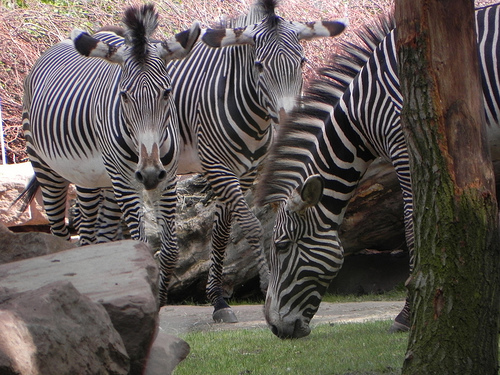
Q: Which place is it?
A: It is a park.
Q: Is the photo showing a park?
A: Yes, it is showing a park.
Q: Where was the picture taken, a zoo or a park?
A: It was taken at a park.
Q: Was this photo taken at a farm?
A: No, the picture was taken in a park.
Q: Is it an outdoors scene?
A: Yes, it is outdoors.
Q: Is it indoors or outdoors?
A: It is outdoors.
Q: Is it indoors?
A: No, it is outdoors.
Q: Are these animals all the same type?
A: Yes, all the animals are zebras.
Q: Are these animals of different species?
A: No, all the animals are zebras.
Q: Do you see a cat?
A: No, there are no cats.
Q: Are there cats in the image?
A: No, there are no cats.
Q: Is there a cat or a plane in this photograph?
A: No, there are no cats or airplanes.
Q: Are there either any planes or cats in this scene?
A: No, there are no cats or planes.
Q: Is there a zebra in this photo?
A: Yes, there is a zebra.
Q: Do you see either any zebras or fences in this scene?
A: Yes, there is a zebra.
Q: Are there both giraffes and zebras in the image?
A: No, there is a zebra but no giraffes.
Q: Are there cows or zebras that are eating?
A: Yes, the zebra is eating.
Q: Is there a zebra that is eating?
A: Yes, there is a zebra that is eating.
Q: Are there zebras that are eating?
A: Yes, there is a zebra that is eating.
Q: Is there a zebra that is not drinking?
A: Yes, there is a zebra that is eating.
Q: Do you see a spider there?
A: No, there are no spiders.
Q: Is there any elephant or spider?
A: No, there are no spiders or elephants.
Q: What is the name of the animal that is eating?
A: The animal is a zebra.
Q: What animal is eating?
A: The animal is a zebra.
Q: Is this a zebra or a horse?
A: This is a zebra.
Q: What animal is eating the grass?
A: The animal is a zebra.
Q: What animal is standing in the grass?
A: The animal is a zebra.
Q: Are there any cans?
A: No, there are no cans.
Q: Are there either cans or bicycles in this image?
A: No, there are no cans or bicycles.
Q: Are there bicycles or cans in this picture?
A: No, there are no cans or bicycles.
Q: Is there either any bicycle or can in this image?
A: No, there are no cans or bicycles.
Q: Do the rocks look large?
A: Yes, the rocks are large.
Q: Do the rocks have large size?
A: Yes, the rocks are large.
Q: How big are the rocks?
A: The rocks are large.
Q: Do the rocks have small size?
A: No, the rocks are large.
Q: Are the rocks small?
A: No, the rocks are large.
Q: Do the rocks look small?
A: No, the rocks are large.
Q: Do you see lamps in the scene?
A: No, there are no lamps.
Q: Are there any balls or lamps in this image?
A: No, there are no lamps or balls.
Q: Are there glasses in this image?
A: No, there are no glasses.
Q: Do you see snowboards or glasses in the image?
A: No, there are no glasses or snowboards.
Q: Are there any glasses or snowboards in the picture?
A: No, there are no glasses or snowboards.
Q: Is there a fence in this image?
A: No, there are no fences.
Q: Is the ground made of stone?
A: Yes, the ground is made of stone.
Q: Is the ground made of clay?
A: No, the ground is made of stone.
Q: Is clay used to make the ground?
A: No, the ground is made of stone.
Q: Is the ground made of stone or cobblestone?
A: The ground is made of stone.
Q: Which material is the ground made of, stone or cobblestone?
A: The ground is made of stone.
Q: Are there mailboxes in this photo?
A: No, there are no mailboxes.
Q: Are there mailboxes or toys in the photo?
A: No, there are no mailboxes or toys.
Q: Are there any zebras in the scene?
A: Yes, there are zebras.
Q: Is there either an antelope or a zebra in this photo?
A: Yes, there are zebras.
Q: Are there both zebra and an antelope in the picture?
A: No, there are zebras but no antelopes.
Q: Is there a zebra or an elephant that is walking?
A: Yes, the zebras are walking.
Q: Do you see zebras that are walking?
A: Yes, there are zebras that are walking.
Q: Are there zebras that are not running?
A: Yes, there are zebras that are walking.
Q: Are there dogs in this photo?
A: No, there are no dogs.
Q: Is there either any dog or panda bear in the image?
A: No, there are no dogs or panda bears.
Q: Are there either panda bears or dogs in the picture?
A: No, there are no dogs or panda bears.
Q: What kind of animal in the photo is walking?
A: The animal is zebras.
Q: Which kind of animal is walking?
A: The animal is zebras.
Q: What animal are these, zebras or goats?
A: These are zebras.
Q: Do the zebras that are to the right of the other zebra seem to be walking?
A: Yes, the zebras are walking.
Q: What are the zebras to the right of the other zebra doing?
A: The zebras are walking.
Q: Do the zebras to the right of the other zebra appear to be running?
A: No, the zebras are walking.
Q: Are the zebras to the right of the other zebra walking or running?
A: The zebras are walking.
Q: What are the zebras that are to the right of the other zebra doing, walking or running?
A: The zebras are walking.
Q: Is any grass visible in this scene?
A: Yes, there is grass.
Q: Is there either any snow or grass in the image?
A: Yes, there is grass.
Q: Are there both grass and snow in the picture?
A: No, there is grass but no snow.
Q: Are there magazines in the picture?
A: No, there are no magazines.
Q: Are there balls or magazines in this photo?
A: No, there are no magazines or balls.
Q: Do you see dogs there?
A: No, there are no dogs.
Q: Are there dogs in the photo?
A: No, there are no dogs.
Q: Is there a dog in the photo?
A: No, there are no dogs.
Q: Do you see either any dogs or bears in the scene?
A: No, there are no dogs or bears.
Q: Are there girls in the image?
A: No, there are no girls.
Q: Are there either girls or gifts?
A: No, there are no girls or gifts.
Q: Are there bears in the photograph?
A: No, there are no bears.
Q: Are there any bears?
A: No, there are no bears.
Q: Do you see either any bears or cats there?
A: No, there are no bears or cats.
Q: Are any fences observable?
A: No, there are no fences.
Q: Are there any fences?
A: No, there are no fences.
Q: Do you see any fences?
A: No, there are no fences.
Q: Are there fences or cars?
A: No, there are no fences or cars.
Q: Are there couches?
A: No, there are no couches.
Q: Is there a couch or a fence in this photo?
A: No, there are no couches or fences.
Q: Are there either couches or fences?
A: No, there are no couches or fences.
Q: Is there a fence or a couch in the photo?
A: No, there are no couches or fences.